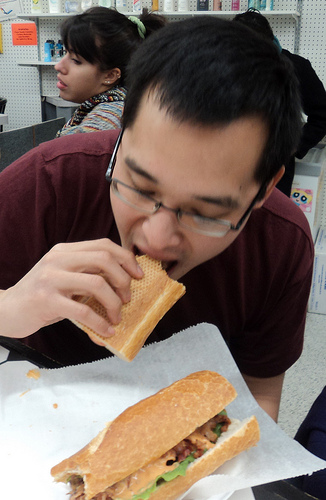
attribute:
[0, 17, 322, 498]
man — eating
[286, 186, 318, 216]
cartoon — kitten, powder puff girl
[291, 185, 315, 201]
hair — yellow, existing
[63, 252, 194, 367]
sandwich — being eaten, bread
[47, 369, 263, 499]
sandwich — large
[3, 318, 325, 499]
paper — white, existing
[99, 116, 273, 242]
glasses — black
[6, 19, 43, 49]
sign — orange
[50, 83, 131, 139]
sweater — colorful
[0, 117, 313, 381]
shirt — burgandy, red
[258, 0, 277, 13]
bottle — blue, white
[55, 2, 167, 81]
hair — black